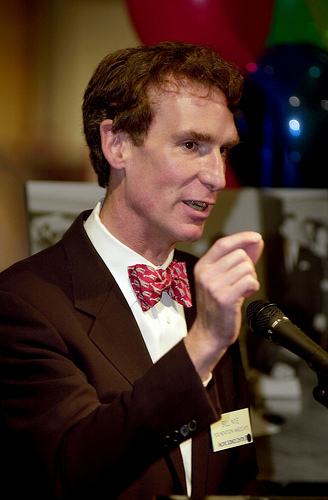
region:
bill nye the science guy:
[64, 53, 267, 388]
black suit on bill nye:
[25, 258, 209, 496]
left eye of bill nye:
[175, 132, 198, 149]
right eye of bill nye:
[216, 140, 231, 160]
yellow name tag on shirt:
[203, 401, 260, 456]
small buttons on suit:
[161, 414, 203, 443]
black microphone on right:
[247, 296, 313, 351]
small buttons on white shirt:
[165, 309, 175, 328]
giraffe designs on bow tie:
[141, 266, 165, 285]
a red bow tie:
[130, 258, 191, 309]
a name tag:
[208, 407, 252, 453]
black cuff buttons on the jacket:
[164, 421, 197, 444]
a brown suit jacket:
[4, 211, 253, 496]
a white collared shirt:
[88, 202, 184, 370]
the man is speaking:
[1, 44, 260, 498]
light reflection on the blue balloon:
[287, 117, 299, 136]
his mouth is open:
[180, 195, 214, 217]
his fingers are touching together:
[209, 231, 264, 268]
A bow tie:
[138, 270, 185, 292]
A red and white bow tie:
[146, 272, 183, 291]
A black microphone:
[252, 301, 273, 323]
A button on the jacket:
[180, 426, 187, 433]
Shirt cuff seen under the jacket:
[205, 381, 208, 382]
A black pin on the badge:
[246, 434, 250, 440]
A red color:
[146, 9, 194, 39]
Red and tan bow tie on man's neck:
[125, 263, 192, 310]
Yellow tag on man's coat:
[213, 406, 254, 450]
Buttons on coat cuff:
[171, 419, 196, 439]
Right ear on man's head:
[98, 118, 124, 167]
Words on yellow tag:
[216, 420, 248, 442]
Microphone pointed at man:
[248, 301, 326, 381]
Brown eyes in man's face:
[185, 141, 228, 155]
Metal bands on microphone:
[266, 313, 287, 334]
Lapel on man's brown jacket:
[65, 233, 144, 381]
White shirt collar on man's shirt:
[92, 199, 188, 305]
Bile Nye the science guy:
[30, 38, 277, 343]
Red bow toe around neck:
[113, 247, 197, 314]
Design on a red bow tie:
[131, 261, 145, 275]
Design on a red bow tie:
[136, 275, 146, 286]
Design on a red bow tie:
[141, 289, 148, 296]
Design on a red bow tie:
[145, 293, 160, 307]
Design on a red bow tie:
[150, 279, 161, 295]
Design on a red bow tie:
[143, 256, 155, 269]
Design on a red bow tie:
[158, 275, 173, 292]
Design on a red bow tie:
[172, 281, 186, 297]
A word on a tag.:
[213, 429, 235, 438]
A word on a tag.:
[233, 424, 259, 432]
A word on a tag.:
[220, 419, 227, 426]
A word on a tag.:
[232, 416, 245, 425]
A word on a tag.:
[214, 434, 250, 443]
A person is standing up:
[10, 33, 275, 497]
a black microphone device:
[243, 295, 326, 382]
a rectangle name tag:
[203, 406, 256, 452]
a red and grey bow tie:
[125, 260, 192, 312]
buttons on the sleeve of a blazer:
[158, 417, 200, 452]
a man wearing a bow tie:
[0, 42, 264, 498]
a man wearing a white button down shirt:
[0, 41, 267, 498]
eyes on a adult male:
[174, 133, 237, 155]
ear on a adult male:
[96, 118, 130, 167]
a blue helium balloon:
[227, 40, 325, 186]